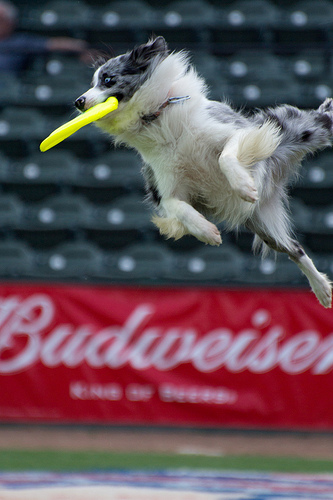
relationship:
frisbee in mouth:
[37, 95, 118, 152] [86, 89, 124, 117]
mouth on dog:
[86, 89, 124, 117] [71, 31, 333, 315]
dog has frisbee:
[71, 31, 333, 315] [37, 95, 118, 152]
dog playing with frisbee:
[64, 30, 331, 314] [37, 95, 118, 152]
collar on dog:
[143, 93, 197, 114] [64, 30, 331, 314]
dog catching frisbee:
[64, 30, 331, 314] [37, 95, 118, 152]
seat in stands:
[19, 148, 80, 181] [1, 2, 330, 285]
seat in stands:
[31, 194, 97, 235] [1, 2, 330, 285]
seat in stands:
[103, 195, 164, 233] [1, 2, 330, 285]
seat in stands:
[106, 243, 176, 281] [1, 2, 330, 285]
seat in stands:
[228, 56, 290, 85] [1, 2, 330, 285]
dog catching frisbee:
[71, 31, 333, 315] [49, 109, 101, 150]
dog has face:
[71, 31, 333, 315] [74, 57, 149, 140]